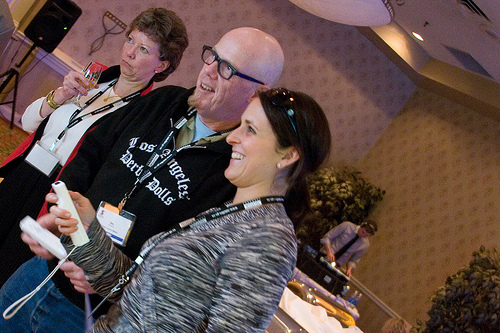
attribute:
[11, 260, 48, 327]
jeans — blue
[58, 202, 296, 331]
shirt — striped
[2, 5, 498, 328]
event — social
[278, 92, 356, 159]
hair — black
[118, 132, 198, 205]
writing — white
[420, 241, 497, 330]
bushes — decorative, inside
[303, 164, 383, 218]
bushes — inside, decorative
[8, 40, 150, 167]
shirt — white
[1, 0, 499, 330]
wallpaper — ornate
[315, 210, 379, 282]
man — bald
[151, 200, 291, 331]
shirt — black and white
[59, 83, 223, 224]
shirt — black